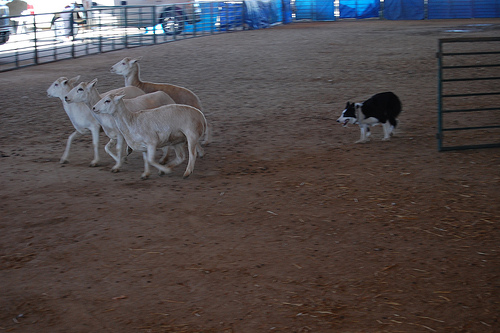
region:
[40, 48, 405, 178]
dog following shorn tan sheep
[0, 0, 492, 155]
open gate in enclosure with metal fencing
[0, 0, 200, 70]
man in bright light between two vehicles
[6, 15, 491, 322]
flat brown ground with pieces of straw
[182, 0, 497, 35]
blue tarp covering railing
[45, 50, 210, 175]
sheep running in a group in same direction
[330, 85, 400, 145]
black and white dog with snarling expression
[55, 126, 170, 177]
slim legs bent at knees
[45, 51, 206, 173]
sheep in rear taller and tanner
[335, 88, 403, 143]
dog in compacted stance with rounded body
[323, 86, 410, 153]
black and white dog herding sheep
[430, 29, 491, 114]
open gate in the corral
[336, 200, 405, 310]
pieces of hay on the ground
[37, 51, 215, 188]
sheep moving away from the dog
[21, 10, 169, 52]
fence of the corral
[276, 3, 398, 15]
blue tarps hanging on the fence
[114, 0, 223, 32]
truck outside the corral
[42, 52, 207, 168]
four sheep in a group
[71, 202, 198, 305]
dirt floor of the corral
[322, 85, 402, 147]
black and white dog in the corral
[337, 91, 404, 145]
Border collie herding sheep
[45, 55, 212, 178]
Sheep being herded by border collie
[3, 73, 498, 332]
Dirt area inside gate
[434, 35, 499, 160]
open gate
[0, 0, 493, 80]
fence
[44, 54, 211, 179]
Four shorn sheep being herded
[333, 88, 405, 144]
panting border collie herding sheep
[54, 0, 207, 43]
gray truck outside fenced area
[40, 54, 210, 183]
herd of sheep being herded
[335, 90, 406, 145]
black and white dog pauses while herding sheep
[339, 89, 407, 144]
black and white dog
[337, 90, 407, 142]
black and white sheepdog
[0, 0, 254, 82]
green metal barnyard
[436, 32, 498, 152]
green barnyard door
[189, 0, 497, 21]
blue fence in the back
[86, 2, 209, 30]
white wagon behind barnyard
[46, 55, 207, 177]
four sheeps without wool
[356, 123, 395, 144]
four white legs of sheepdog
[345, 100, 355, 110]
two small black little ears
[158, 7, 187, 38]
back black wheel of car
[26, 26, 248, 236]
sheep running in a field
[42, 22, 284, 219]
sheep running in dirt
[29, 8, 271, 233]
sheep that are fenced in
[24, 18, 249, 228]
sheep running in a fenced in area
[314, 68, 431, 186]
a dog that is running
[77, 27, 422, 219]
a dog running after sheep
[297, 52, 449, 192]
a dog running in a dirt field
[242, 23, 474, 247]
a dog in a dirt field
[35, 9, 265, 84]
a metal fence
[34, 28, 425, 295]
sheep behind a metal fence